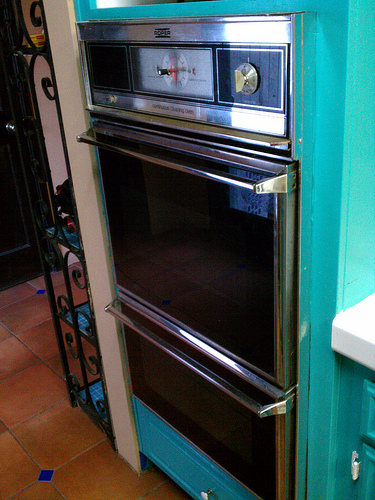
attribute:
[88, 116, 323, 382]
oven — silver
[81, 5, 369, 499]
wall — chrome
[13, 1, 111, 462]
shelf — rod , iron , blue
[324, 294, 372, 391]
counter — white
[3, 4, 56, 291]
door — black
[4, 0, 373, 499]
kitchen — painted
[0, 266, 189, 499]
flooring — brown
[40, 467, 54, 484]
tile — blue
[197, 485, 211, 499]
handle — white